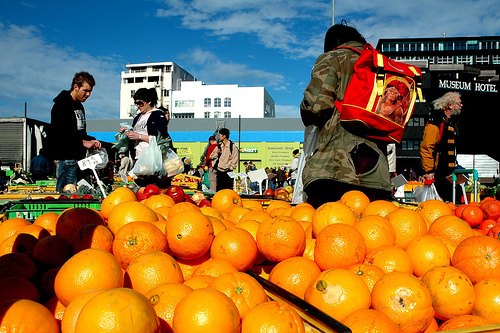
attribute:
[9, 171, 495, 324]
oranges — alot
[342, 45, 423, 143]
book bag — red, yellow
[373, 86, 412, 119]
character — small soldiers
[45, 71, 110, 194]
man — looking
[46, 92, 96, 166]
hoodie — black, graphic, man's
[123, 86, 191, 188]
woman — conducting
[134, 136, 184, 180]
bags — plastic, white, grocery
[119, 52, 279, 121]
building — white, wide, square shaped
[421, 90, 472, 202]
man — old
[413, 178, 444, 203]
bags — grocery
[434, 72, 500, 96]
sign — white, museum hotel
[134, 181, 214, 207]
apples — few, red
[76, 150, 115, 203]
sign — small, white, price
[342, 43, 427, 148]
back pack — red, yellow, graphic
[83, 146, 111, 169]
bag — plastic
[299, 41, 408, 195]
jacket — army, fatigue, man's, camo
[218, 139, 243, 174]
jacket — brown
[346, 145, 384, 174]
patch — black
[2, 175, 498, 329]
display — oranges, sizable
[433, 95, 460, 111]
hair — long, gray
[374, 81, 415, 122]
decal — picture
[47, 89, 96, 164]
sweater — long, long sleeve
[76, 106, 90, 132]
design — white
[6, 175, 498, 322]
pile — oranges, large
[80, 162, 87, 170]
number — 8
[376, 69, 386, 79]
snap — black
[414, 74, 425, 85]
snap — black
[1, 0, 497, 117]
sky — blue, cloudy, white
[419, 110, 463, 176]
jacket — orange, striped, black, man's